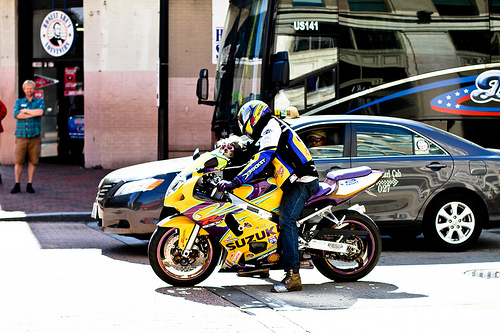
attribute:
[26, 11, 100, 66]
sign — round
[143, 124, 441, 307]
motorcycle — Suzuki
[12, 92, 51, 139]
shirt — blue 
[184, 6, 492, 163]
bus — number US141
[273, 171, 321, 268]
jeans — blue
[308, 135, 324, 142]
sun glasses — black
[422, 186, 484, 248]
tire — black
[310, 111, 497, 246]
car — shinny, grey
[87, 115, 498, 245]
sedan — black, four door, taxi cab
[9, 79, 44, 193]
man — plaid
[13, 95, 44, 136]
shirt — blue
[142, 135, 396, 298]
bike — black